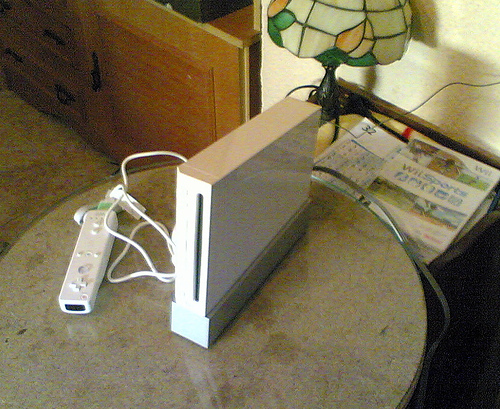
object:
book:
[312, 117, 407, 202]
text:
[395, 163, 469, 207]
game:
[57, 96, 323, 350]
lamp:
[265, 0, 413, 67]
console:
[170, 95, 323, 348]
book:
[358, 139, 500, 266]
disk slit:
[194, 193, 203, 302]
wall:
[257, 4, 499, 169]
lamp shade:
[265, 0, 413, 67]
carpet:
[0, 82, 128, 257]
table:
[0, 163, 429, 409]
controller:
[58, 210, 119, 315]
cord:
[103, 150, 189, 283]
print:
[403, 163, 415, 172]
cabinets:
[0, 0, 261, 166]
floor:
[2, 80, 122, 252]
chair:
[312, 111, 500, 280]